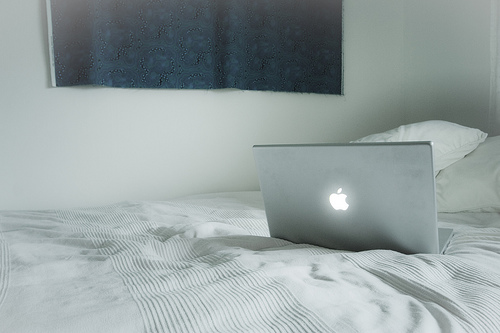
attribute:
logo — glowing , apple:
[327, 185, 349, 210]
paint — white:
[52, 108, 102, 141]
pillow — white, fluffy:
[436, 133, 498, 227]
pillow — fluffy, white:
[347, 117, 489, 175]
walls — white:
[3, 2, 493, 189]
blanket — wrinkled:
[33, 190, 336, 330]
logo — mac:
[313, 187, 353, 214]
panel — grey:
[46, 0, 348, 97]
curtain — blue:
[47, 3, 346, 96]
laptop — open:
[231, 120, 456, 272]